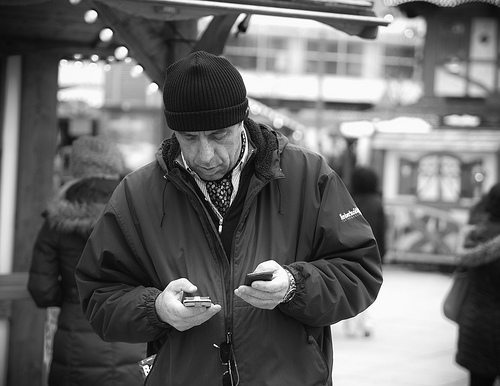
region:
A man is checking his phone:
[21, 41, 451, 359]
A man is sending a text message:
[6, 35, 479, 353]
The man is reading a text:
[11, 21, 482, 366]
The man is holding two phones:
[23, 12, 469, 353]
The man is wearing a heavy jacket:
[25, 13, 460, 355]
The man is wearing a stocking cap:
[16, 0, 481, 377]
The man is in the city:
[36, 23, 491, 375]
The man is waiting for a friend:
[35, 15, 465, 366]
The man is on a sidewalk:
[26, 18, 454, 375]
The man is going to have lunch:
[9, 10, 467, 370]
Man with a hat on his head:
[158, 46, 255, 203]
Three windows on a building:
[219, 26, 450, 90]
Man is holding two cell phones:
[73, 45, 381, 383]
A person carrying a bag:
[442, 184, 497, 381]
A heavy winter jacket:
[23, 173, 149, 382]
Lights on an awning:
[66, 0, 161, 99]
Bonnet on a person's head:
[69, 131, 126, 187]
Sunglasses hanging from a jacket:
[207, 321, 244, 383]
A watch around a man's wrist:
[282, 263, 304, 313]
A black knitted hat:
[154, 43, 253, 134]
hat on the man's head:
[167, 42, 246, 139]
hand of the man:
[233, 249, 303, 326]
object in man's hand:
[170, 276, 222, 328]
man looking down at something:
[156, 70, 291, 205]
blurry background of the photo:
[398, 101, 452, 191]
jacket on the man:
[246, 138, 332, 258]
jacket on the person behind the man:
[18, 170, 98, 312]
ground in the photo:
[373, 356, 413, 383]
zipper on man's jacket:
[206, 224, 255, 316]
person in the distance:
[347, 155, 409, 209]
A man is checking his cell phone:
[21, 15, 453, 372]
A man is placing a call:
[35, 32, 470, 360]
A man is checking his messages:
[60, 40, 447, 350]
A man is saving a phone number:
[30, 18, 441, 370]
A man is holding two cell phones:
[35, 32, 443, 362]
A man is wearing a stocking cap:
[60, 20, 430, 361]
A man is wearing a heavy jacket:
[62, 20, 432, 365]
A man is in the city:
[40, 43, 485, 383]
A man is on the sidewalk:
[46, 21, 447, 337]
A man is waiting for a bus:
[55, 28, 441, 382]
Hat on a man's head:
[159, 48, 250, 179]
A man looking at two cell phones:
[74, 49, 384, 382]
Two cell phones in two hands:
[157, 257, 286, 333]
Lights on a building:
[70, 0, 159, 98]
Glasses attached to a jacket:
[213, 331, 240, 383]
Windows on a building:
[224, 23, 426, 84]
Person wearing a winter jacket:
[27, 133, 151, 380]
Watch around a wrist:
[280, 265, 299, 307]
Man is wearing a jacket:
[76, 49, 382, 381]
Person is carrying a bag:
[440, 184, 498, 383]